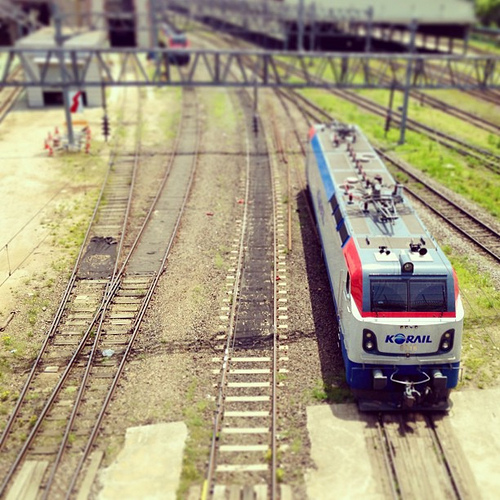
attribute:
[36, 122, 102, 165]
cones — orange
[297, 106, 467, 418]
train — red, white, blue, gray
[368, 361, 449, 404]
link — metal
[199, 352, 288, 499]
rails — wood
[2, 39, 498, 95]
rail — metal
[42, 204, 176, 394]
tracks — crossing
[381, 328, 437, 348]
logo — blue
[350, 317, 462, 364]
front — white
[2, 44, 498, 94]
railing — metal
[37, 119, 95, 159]
cones — orange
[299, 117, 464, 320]
stripe — blue, red